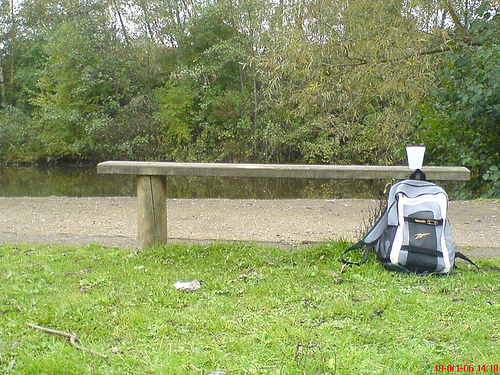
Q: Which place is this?
A: It is a park.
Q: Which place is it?
A: It is a park.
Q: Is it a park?
A: Yes, it is a park.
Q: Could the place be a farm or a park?
A: It is a park.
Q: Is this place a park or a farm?
A: It is a park.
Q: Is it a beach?
A: No, it is a park.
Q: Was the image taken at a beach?
A: No, the picture was taken in a park.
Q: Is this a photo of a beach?
A: No, the picture is showing a park.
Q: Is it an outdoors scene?
A: Yes, it is outdoors.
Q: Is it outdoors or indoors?
A: It is outdoors.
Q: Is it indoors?
A: No, it is outdoors.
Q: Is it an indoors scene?
A: No, it is outdoors.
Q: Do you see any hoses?
A: No, there are no hoses.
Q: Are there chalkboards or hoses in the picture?
A: No, there are no hoses or chalkboards.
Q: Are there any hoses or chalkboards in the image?
A: No, there are no hoses or chalkboards.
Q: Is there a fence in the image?
A: No, there are no fences.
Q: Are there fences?
A: No, there are no fences.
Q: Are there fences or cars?
A: No, there are no fences or cars.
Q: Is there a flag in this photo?
A: No, there are no flags.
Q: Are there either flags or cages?
A: No, there are no flags or cages.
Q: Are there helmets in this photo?
A: No, there are no helmets.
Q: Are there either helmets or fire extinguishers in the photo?
A: No, there are no helmets or fire extinguishers.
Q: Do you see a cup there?
A: Yes, there is a cup.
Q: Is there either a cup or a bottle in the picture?
A: Yes, there is a cup.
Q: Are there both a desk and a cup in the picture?
A: No, there is a cup but no desks.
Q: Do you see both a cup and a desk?
A: No, there is a cup but no desks.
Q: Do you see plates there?
A: No, there are no plates.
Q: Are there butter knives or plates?
A: No, there are no plates or butter knives.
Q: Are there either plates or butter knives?
A: No, there are no plates or butter knives.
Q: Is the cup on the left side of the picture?
A: No, the cup is on the right of the image.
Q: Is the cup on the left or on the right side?
A: The cup is on the right of the image.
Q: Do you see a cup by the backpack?
A: Yes, there is a cup by the backpack.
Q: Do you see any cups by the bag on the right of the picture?
A: Yes, there is a cup by the backpack.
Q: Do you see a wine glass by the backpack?
A: No, there is a cup by the backpack.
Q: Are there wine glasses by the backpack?
A: No, there is a cup by the backpack.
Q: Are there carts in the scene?
A: No, there are no carts.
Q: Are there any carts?
A: No, there are no carts.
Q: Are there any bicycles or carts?
A: No, there are no carts or bicycles.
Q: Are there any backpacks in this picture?
A: Yes, there is a backpack.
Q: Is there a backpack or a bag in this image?
A: Yes, there is a backpack.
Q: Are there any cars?
A: No, there are no cars.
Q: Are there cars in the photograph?
A: No, there are no cars.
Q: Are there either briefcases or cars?
A: No, there are no cars or briefcases.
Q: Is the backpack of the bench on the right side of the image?
A: Yes, the backpack is on the right of the image.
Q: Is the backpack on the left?
A: No, the backpack is on the right of the image.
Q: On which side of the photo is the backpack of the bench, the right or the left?
A: The backpack is on the right of the image.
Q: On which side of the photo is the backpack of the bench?
A: The backpack is on the right of the image.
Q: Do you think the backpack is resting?
A: Yes, the backpack is resting.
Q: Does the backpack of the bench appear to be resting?
A: Yes, the backpack is resting.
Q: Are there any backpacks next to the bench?
A: Yes, there is a backpack next to the bench.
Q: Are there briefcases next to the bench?
A: No, there is a backpack next to the bench.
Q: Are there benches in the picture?
A: Yes, there is a bench.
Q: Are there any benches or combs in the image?
A: Yes, there is a bench.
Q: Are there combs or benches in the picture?
A: Yes, there is a bench.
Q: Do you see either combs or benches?
A: Yes, there is a bench.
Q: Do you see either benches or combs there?
A: Yes, there is a bench.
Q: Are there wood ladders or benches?
A: Yes, there is a wood bench.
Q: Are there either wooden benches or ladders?
A: Yes, there is a wood bench.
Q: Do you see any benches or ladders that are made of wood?
A: Yes, the bench is made of wood.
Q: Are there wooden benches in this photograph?
A: Yes, there is a wood bench.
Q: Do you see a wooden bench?
A: Yes, there is a wood bench.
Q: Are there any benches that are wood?
A: Yes, there is a wood bench.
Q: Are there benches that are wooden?
A: Yes, there is a bench that is wooden.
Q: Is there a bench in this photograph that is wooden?
A: Yes, there is a bench that is wooden.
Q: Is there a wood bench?
A: Yes, there is a bench that is made of wood.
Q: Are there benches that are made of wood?
A: Yes, there is a bench that is made of wood.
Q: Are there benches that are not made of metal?
A: Yes, there is a bench that is made of wood.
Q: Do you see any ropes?
A: No, there are no ropes.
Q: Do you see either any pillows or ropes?
A: No, there are no ropes or pillows.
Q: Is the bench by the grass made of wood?
A: Yes, the bench is made of wood.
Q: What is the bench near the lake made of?
A: The bench is made of wood.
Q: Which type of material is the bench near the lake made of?
A: The bench is made of wood.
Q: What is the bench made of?
A: The bench is made of wood.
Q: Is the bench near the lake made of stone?
A: No, the bench is made of wood.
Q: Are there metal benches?
A: No, there is a bench but it is made of wood.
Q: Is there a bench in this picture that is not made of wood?
A: No, there is a bench but it is made of wood.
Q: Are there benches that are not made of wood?
A: No, there is a bench but it is made of wood.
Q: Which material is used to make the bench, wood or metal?
A: The bench is made of wood.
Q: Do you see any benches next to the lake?
A: Yes, there is a bench next to the lake.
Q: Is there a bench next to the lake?
A: Yes, there is a bench next to the lake.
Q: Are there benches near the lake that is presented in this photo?
A: Yes, there is a bench near the lake.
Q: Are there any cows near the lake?
A: No, there is a bench near the lake.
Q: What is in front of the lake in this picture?
A: The bench is in front of the lake.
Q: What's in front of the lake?
A: The bench is in front of the lake.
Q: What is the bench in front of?
A: The bench is in front of the lake.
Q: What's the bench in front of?
A: The bench is in front of the lake.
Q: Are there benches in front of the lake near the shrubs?
A: Yes, there is a bench in front of the lake.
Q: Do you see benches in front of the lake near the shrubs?
A: Yes, there is a bench in front of the lake.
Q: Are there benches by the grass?
A: Yes, there is a bench by the grass.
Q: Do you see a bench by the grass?
A: Yes, there is a bench by the grass.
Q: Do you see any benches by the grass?
A: Yes, there is a bench by the grass.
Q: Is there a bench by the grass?
A: Yes, there is a bench by the grass.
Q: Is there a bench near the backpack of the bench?
A: Yes, there is a bench near the backpack.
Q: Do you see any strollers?
A: No, there are no strollers.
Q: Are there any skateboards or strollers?
A: No, there are no strollers or skateboards.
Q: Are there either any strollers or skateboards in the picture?
A: No, there are no strollers or skateboards.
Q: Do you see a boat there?
A: No, there are no boats.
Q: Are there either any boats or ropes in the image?
A: No, there are no boats or ropes.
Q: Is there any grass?
A: Yes, there is grass.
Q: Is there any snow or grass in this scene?
A: Yes, there is grass.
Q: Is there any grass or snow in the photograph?
A: Yes, there is grass.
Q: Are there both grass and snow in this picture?
A: No, there is grass but no snow.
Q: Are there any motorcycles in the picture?
A: No, there are no motorcycles.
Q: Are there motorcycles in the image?
A: No, there are no motorcycles.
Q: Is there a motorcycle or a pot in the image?
A: No, there are no motorcycles or pots.